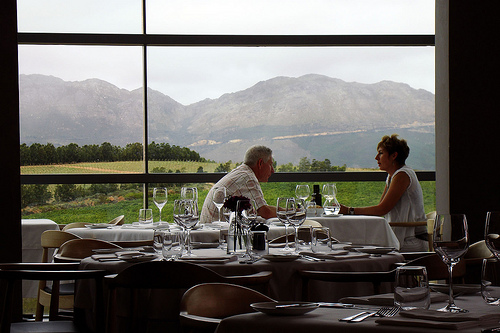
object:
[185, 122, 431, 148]
road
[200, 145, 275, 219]
man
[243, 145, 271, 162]
hair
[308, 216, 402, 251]
table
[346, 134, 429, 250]
woman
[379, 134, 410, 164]
hair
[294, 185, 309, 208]
glass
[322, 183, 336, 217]
glass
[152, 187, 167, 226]
glass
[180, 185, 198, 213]
glass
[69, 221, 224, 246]
table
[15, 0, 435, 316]
window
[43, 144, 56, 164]
tree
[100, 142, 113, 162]
tree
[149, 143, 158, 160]
tree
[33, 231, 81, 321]
chair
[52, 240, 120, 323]
chair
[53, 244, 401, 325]
table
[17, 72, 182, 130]
mountain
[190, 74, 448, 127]
mountain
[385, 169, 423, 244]
shirt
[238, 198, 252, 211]
flower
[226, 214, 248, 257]
vase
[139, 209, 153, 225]
glass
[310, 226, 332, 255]
glass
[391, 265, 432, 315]
glass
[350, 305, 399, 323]
silverware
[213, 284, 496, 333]
table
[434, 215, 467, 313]
glass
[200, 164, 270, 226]
shirt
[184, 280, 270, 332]
seat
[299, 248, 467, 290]
seat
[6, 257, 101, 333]
seat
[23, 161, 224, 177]
crops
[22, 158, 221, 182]
field